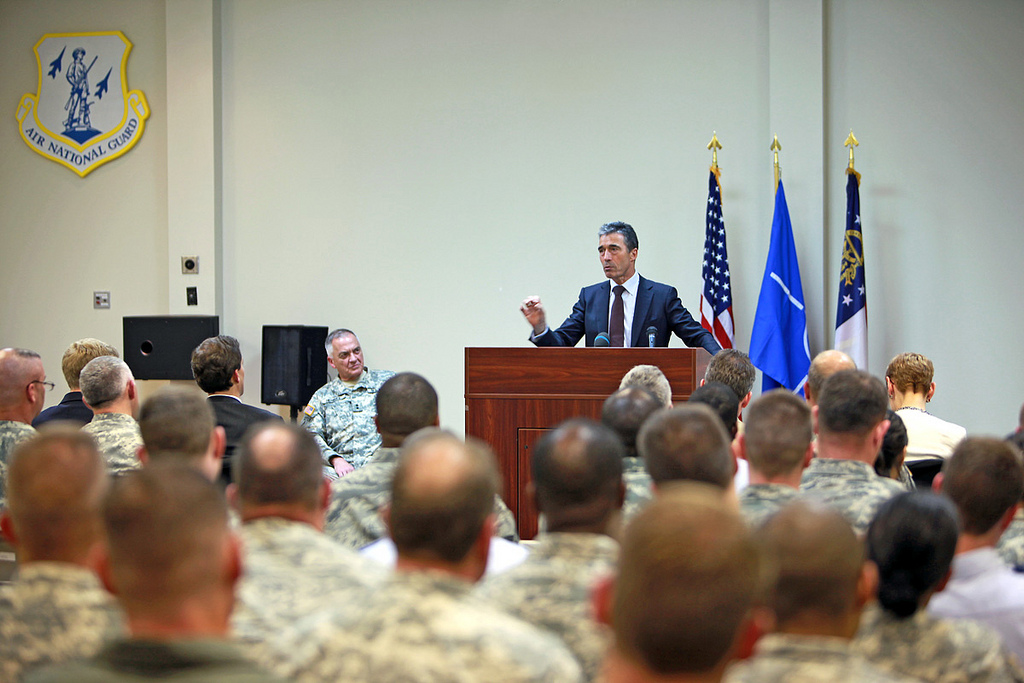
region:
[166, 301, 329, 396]
black speakers next to the soldier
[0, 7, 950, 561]
the man is giving a speech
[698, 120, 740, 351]
The flag of the United State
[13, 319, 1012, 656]
Man and women in uniform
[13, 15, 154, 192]
Logo mounted on a wall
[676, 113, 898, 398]
Three different flags next to each other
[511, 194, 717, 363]
A man speaking at a podium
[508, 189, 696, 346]
A man in a suit and tie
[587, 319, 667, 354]
Microphones on a speaker's podium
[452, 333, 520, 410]
Corner of wooden speaker's podium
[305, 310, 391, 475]
A man in uniform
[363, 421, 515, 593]
A man seen from the back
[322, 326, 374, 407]
man looking to his left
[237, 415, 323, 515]
back of balding man's head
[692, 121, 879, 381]
three flags against the wall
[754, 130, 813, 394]
blue and white flag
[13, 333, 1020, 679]
group of individuals facing a gesturing man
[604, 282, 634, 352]
man wearing dark tie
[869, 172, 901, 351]
shadow on wall behind flag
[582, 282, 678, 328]
man wearing dark suit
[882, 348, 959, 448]
woman with short hair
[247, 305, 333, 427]
black speaker near man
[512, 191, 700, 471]
man standing behind a podium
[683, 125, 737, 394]
American flag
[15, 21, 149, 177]
military sign for the Air National Guard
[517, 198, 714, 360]
man wearing a suit jacket and tie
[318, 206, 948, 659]
a man speaking to a crowd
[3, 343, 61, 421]
man wearing glasses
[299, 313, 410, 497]
a man wearing a military uniform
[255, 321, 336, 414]
black speaker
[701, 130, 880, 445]
three flags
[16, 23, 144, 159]
A yellow and white Air National Guard Plaque on the wall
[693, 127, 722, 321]
American Flag behind the man speaking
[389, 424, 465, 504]
A small bald spot on a mans head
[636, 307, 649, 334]
A microphone directed at the man speaking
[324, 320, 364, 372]
A mans face looking at the gentlemen speaking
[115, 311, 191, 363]
A black square speaker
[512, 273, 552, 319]
The mans hand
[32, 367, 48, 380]
a mans glasses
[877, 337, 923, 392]
A womans head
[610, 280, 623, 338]
The mans dark tie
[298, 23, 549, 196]
The wall is white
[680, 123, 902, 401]
Three flags next to each other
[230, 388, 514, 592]
Two bald heads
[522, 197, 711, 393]
Man giving a speech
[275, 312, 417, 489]
Man wearing an army uniform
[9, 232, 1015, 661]
Men listening to a speech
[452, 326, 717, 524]
A brown wooden platform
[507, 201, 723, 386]
Man wearing a suit and tie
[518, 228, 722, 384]
Man has his arm raised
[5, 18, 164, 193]
A picture hanging on the wall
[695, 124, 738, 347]
flag of the United States of America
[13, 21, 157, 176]
Air National Guard seal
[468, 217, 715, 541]
male speaker behind a podium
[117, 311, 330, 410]
black speakers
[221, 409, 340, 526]
man with a bald spot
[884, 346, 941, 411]
woman with a short haircut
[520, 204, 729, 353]
man wearing a blue suit and tie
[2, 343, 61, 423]
man wearing eyeglasses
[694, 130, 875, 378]
three different flags